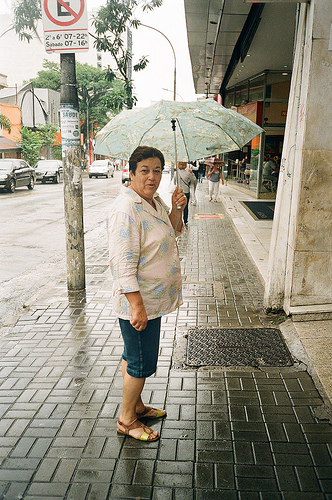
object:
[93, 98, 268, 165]
umbrella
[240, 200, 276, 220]
mat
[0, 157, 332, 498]
ground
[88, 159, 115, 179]
van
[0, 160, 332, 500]
road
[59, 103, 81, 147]
flyer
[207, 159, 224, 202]
woman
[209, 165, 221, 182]
shirt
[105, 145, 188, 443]
person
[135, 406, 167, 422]
sandal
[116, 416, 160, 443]
sandal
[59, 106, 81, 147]
sign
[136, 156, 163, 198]
face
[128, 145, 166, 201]
head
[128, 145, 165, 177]
hair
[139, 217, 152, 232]
flower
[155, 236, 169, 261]
flower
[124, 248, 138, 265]
flower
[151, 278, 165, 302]
flower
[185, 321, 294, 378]
grate cover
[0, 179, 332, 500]
bricks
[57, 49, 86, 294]
pole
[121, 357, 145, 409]
calf muscles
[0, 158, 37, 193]
car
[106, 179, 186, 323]
shirt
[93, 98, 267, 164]
blue umbrella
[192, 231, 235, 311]
red hat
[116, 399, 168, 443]
brown sandals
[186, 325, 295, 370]
man hole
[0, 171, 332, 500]
sidewalk